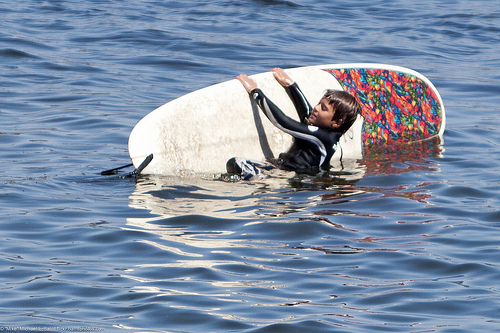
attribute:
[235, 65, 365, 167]
kid — smiling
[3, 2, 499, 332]
water — blue, calm, reflecting, wavy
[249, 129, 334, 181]
wetsuit — black, white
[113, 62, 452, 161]
surfboard — colorful, white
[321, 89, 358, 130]
hair — brown, wet, black